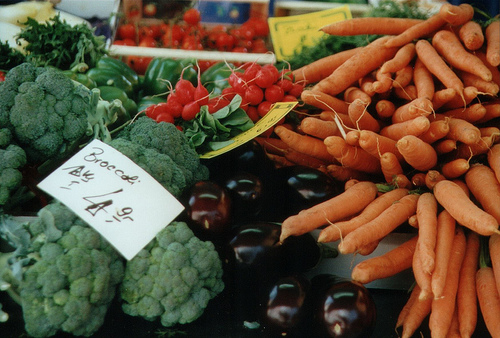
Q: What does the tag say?
A: Broccoli.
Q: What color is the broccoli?
A: Green.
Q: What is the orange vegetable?
A: Carrot.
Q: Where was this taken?
A: Farmer's market.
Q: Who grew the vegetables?
A: A farmer.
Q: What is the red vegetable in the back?
A: Tomato.